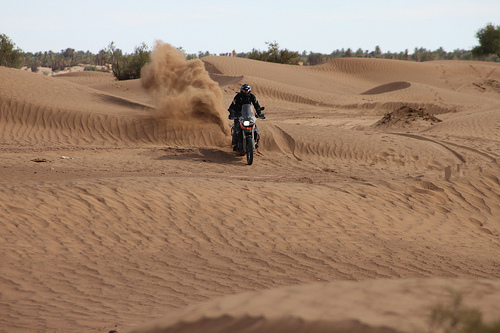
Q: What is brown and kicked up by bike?
A: Dirt.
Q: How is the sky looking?
A: Hazy blue.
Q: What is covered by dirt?
A: Track.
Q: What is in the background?
A: Trees.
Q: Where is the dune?
A: Behind biker.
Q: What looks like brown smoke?
A: Dirt.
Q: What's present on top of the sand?
A: Dunes.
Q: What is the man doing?
A: Riding his motorcycle.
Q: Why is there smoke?
A: The pile of sand was hit by the motorcycle.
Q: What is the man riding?
A: A motorcycle.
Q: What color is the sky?
A: Blue.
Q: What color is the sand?
A: Tan.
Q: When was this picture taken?
A: Daytime.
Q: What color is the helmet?
A: Black.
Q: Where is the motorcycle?
A: On the sand.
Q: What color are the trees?
A: Green.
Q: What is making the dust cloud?
A: The motorcycle.